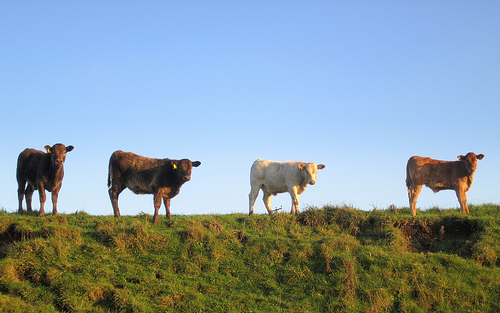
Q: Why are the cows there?
A: For food.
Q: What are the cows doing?
A: Grazing.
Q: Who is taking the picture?
A: A person.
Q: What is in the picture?
A: Four cows.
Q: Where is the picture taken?
A: In a field.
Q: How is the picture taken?
A: From a distance.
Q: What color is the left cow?
A: Brown.